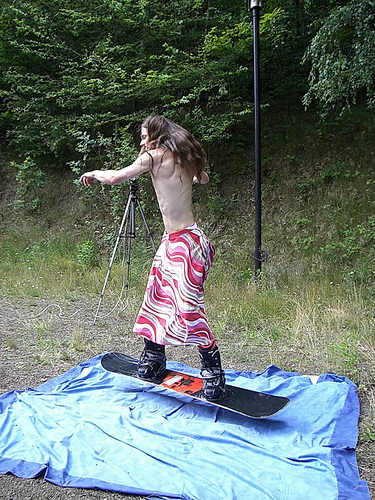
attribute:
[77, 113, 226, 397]
person — posing, skinny, muscular, shirtless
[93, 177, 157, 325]
camera — black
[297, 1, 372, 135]
branches — drooping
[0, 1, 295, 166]
branches — straight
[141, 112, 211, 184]
hair — long, dark, brown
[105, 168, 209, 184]
elbows — bent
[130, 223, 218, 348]
skirt — long, red, pink, white, wavy, striped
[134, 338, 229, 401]
boots — black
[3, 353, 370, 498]
blanket — blue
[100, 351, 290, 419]
snowboard — black, orange, hovering, red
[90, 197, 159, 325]
tripod — standing, gray, metal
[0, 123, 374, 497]
ground — dirt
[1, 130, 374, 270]
plants — short, green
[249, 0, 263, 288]
pole — black, long, metal, steel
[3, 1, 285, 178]
tree — green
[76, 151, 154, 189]
left arm — extended